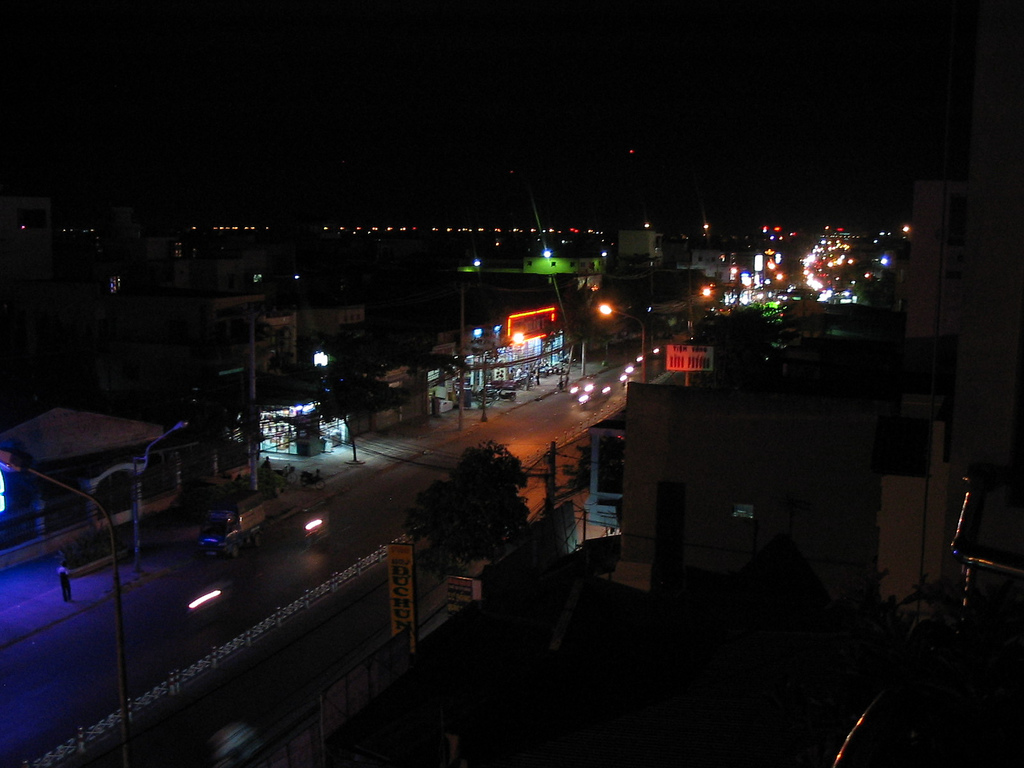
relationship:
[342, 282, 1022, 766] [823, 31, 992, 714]
buildings on right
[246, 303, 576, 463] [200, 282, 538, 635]
set of buildings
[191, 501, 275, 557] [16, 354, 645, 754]
truck on street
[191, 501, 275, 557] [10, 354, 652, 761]
truck on road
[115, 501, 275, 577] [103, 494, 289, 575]
truck on curb